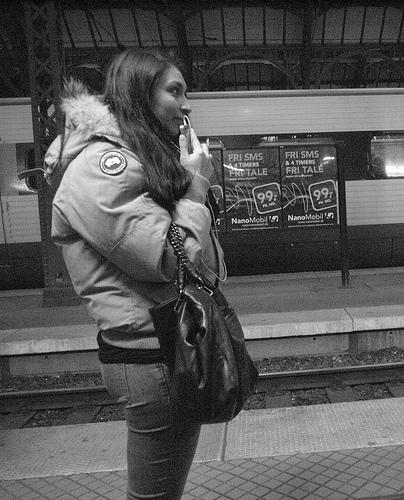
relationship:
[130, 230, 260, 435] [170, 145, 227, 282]
purse on arm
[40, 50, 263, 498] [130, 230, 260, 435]
girl carrying purse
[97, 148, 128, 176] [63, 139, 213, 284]
logo on coat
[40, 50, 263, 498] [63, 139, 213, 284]
girl wearing coat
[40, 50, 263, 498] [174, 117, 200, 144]
girl carrying cellphone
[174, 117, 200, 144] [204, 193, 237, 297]
cellphone has jack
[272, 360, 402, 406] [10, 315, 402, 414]
tracks on ground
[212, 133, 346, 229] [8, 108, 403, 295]
advertisement on train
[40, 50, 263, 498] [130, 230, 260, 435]
girl has handbag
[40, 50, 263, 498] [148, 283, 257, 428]
girl holding bag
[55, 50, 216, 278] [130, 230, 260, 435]
girl holding purse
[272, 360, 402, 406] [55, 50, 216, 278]
tracks behind girl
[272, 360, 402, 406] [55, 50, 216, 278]
tracks by girl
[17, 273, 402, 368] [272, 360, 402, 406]
platform by tracks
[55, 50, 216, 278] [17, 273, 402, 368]
girl near platform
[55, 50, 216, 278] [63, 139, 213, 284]
girl wear coat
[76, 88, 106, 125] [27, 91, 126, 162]
fur on hood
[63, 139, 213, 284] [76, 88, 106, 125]
coat has fur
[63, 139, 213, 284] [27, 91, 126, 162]
coat has hood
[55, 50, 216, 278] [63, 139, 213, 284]
girl wearing coat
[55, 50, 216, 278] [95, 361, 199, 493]
girl wearing jeans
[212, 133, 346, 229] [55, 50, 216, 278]
advertisement by girl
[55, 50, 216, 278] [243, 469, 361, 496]
girl on tiles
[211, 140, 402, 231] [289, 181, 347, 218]
window has 99 cents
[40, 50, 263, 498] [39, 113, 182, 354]
girl wearing jacket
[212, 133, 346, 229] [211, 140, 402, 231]
advertisement on window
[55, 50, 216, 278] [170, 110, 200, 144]
girl has cellphone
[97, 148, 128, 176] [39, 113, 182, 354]
logo on jacket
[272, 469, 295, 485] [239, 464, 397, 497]
pattern on sidewalk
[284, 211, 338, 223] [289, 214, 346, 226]
words says nano mobile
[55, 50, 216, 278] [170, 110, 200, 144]
girl holding cellphone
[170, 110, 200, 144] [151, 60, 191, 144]
cellphone to face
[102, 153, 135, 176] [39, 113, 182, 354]
logo on jacket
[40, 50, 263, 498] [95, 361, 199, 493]
girl wearing pants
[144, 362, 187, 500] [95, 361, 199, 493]
crease in pant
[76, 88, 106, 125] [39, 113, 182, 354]
fur on jacket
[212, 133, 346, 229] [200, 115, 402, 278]
advertisements in background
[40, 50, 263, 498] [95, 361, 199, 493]
girl wearing jeans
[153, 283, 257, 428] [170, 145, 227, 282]
bag on arm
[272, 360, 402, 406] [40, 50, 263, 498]
tracks beside girl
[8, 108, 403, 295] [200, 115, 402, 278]
train in background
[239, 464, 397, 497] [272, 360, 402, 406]
sidewalk beside tracks